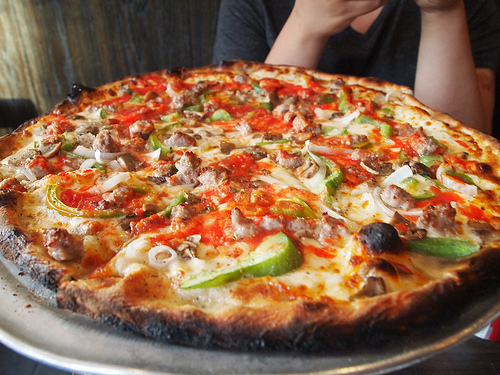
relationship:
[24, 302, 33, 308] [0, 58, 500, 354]
crumb lying on top of crust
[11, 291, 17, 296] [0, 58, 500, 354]
crumb lying on top of crust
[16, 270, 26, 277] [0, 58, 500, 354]
crumb lying on top of crust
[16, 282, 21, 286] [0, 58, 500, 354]
crumb lying on top of crust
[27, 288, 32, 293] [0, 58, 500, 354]
crumb lying on top of crust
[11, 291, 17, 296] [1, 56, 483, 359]
crumb fallen off crust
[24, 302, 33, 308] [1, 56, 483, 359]
crumb fallen off crust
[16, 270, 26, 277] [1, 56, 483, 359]
crumb fallen off crust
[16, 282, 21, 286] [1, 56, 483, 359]
crumb fallen off crust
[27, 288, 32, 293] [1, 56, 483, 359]
crumb fallen off crust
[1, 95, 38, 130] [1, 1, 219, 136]
shadow casted on wall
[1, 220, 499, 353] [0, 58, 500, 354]
crust on crust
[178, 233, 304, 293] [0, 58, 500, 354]
green pepper on crust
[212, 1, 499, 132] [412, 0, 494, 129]
person has arm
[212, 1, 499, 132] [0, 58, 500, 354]
person sitting near crust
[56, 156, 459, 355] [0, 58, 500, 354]
slice on crust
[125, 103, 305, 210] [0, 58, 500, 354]
cheese on crust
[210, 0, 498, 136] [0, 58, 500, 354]
person sitting near crust